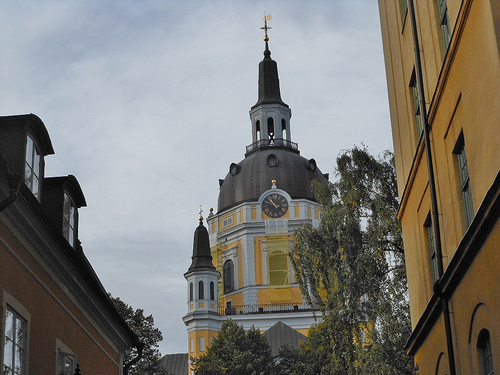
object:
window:
[432, 0, 452, 57]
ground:
[416, 127, 451, 159]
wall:
[201, 201, 322, 313]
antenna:
[259, 11, 272, 56]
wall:
[187, 322, 372, 374]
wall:
[2, 251, 132, 375]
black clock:
[262, 193, 288, 219]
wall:
[246, 166, 313, 262]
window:
[422, 211, 442, 286]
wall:
[245, 201, 309, 314]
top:
[245, 196, 312, 218]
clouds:
[2, 2, 394, 357]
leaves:
[187, 142, 422, 375]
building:
[0, 113, 143, 374]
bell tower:
[205, 14, 376, 363]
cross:
[259, 9, 272, 40]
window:
[269, 250, 289, 287]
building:
[181, 14, 378, 375]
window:
[452, 131, 475, 234]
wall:
[244, 162, 316, 313]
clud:
[123, 176, 191, 288]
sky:
[0, 0, 380, 355]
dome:
[217, 146, 332, 214]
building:
[376, 0, 500, 375]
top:
[248, 22, 292, 147]